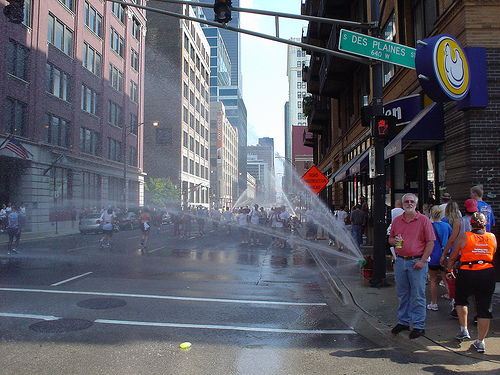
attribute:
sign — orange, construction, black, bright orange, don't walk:
[296, 163, 330, 199]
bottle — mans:
[393, 232, 404, 251]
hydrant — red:
[358, 252, 375, 286]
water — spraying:
[120, 126, 369, 279]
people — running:
[97, 208, 119, 251]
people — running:
[133, 206, 156, 258]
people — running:
[3, 204, 26, 254]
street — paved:
[1, 214, 446, 374]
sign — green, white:
[335, 26, 419, 73]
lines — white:
[2, 284, 329, 309]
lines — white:
[2, 310, 362, 337]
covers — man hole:
[27, 315, 94, 338]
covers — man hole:
[74, 291, 128, 314]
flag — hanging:
[2, 134, 36, 163]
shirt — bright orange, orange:
[454, 228, 498, 272]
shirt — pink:
[389, 211, 438, 259]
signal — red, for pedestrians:
[375, 116, 389, 138]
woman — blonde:
[421, 203, 458, 316]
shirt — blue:
[426, 219, 453, 267]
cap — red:
[463, 196, 478, 214]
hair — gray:
[401, 193, 422, 204]